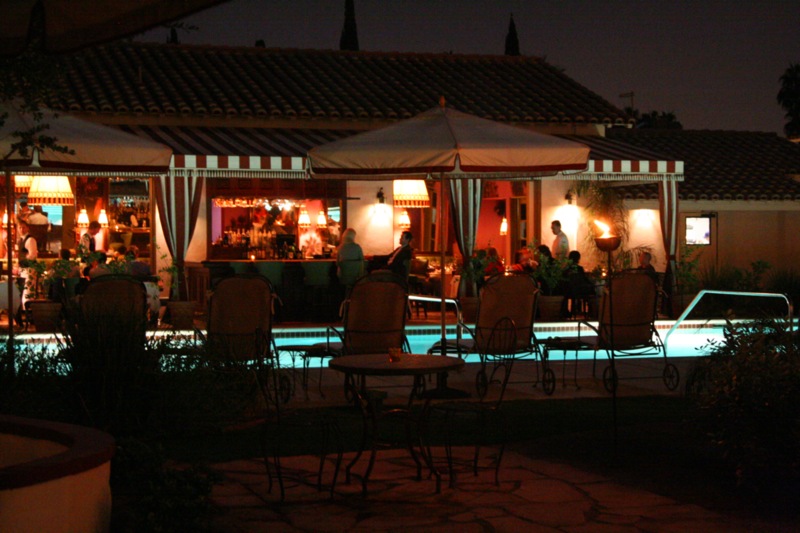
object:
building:
[0, 314, 800, 533]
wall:
[151, 176, 798, 298]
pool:
[0, 319, 800, 377]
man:
[368, 231, 414, 280]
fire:
[593, 220, 615, 239]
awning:
[0, 123, 686, 316]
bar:
[167, 154, 306, 172]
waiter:
[79, 221, 102, 263]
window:
[686, 216, 712, 246]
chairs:
[54, 269, 679, 402]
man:
[551, 221, 569, 262]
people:
[336, 228, 415, 297]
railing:
[663, 289, 791, 354]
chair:
[535, 268, 679, 394]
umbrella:
[304, 95, 590, 400]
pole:
[439, 181, 445, 355]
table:
[326, 353, 465, 501]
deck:
[0, 354, 800, 533]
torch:
[594, 220, 621, 252]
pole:
[608, 252, 617, 432]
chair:
[426, 270, 555, 399]